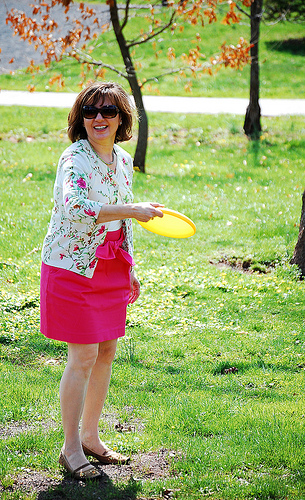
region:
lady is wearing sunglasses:
[61, 94, 173, 191]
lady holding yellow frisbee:
[43, 59, 209, 242]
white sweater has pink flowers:
[56, 80, 173, 267]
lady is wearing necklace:
[49, 61, 152, 181]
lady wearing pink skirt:
[48, 79, 198, 354]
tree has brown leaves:
[33, 0, 236, 131]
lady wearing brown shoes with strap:
[60, 83, 160, 489]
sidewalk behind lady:
[47, 84, 211, 171]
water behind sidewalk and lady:
[1, 9, 179, 132]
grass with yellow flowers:
[136, 237, 273, 326]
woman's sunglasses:
[77, 101, 117, 119]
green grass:
[147, 278, 302, 435]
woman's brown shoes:
[58, 450, 129, 480]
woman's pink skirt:
[43, 275, 127, 342]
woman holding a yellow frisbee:
[64, 81, 194, 332]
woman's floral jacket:
[58, 142, 135, 274]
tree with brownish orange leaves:
[19, 7, 151, 82]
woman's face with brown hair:
[70, 84, 133, 142]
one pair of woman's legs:
[61, 341, 114, 436]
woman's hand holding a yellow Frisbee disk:
[134, 199, 185, 236]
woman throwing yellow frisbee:
[37, 96, 198, 380]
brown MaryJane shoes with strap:
[45, 423, 133, 484]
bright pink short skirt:
[32, 277, 136, 435]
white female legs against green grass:
[36, 353, 130, 436]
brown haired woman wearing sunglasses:
[57, 83, 139, 140]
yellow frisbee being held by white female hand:
[140, 211, 205, 242]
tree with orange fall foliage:
[43, 9, 259, 73]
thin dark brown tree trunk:
[227, 1, 277, 142]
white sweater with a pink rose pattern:
[34, 140, 147, 271]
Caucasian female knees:
[49, 340, 120, 379]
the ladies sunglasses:
[81, 105, 118, 118]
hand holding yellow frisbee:
[131, 205, 195, 234]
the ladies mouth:
[93, 125, 108, 131]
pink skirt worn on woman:
[58, 277, 121, 325]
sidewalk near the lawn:
[159, 97, 229, 110]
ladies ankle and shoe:
[55, 449, 96, 477]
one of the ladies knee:
[75, 350, 100, 372]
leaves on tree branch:
[186, 43, 248, 72]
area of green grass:
[191, 138, 279, 217]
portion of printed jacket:
[56, 214, 92, 258]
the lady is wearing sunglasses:
[66, 81, 135, 144]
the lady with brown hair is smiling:
[66, 81, 137, 144]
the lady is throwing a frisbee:
[37, 81, 196, 286]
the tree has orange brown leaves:
[6, 1, 247, 178]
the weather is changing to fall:
[3, 0, 259, 172]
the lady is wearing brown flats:
[53, 436, 130, 483]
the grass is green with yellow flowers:
[138, 238, 303, 437]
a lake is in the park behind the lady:
[2, 3, 141, 187]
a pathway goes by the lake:
[1, 68, 303, 168]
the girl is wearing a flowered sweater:
[42, 87, 135, 275]